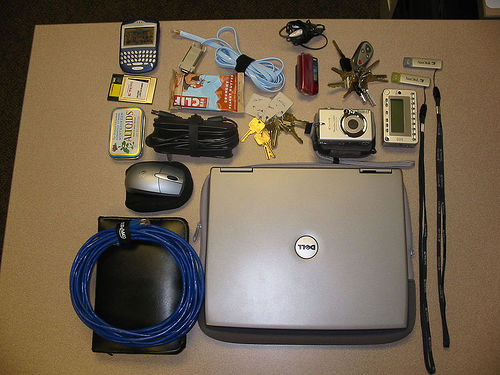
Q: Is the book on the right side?
A: No, the book is on the left of the image.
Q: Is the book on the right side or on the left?
A: The book is on the left of the image.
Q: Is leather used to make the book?
A: Yes, the book is made of leather.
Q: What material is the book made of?
A: The book is made of leather.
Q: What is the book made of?
A: The book is made of leather.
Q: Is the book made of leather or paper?
A: The book is made of leather.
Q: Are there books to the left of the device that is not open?
A: Yes, there is a book to the left of the laptop computer.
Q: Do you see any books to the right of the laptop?
A: No, the book is to the left of the laptop.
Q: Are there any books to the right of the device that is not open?
A: No, the book is to the left of the laptop.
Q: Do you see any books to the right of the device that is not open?
A: No, the book is to the left of the laptop.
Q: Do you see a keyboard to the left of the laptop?
A: No, there is a book to the left of the laptop.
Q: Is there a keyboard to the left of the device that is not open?
A: No, there is a book to the left of the laptop.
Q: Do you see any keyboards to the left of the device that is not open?
A: No, there is a book to the left of the laptop.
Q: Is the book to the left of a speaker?
A: No, the book is to the left of the laptop.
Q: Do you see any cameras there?
A: Yes, there is a camera.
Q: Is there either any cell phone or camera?
A: Yes, there is a camera.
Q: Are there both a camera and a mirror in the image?
A: No, there is a camera but no mirrors.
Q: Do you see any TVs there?
A: No, there are no tvs.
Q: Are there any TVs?
A: No, there are no tvs.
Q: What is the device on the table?
A: The device is a camera.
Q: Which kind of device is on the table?
A: The device is a camera.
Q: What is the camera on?
A: The camera is on the table.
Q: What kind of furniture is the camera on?
A: The camera is on the table.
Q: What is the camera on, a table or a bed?
A: The camera is on a table.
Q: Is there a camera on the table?
A: Yes, there is a camera on the table.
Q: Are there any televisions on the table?
A: No, there is a camera on the table.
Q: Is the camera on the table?
A: Yes, the camera is on the table.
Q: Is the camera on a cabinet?
A: No, the camera is on the table.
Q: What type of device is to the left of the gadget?
A: The device is a camera.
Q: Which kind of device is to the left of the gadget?
A: The device is a camera.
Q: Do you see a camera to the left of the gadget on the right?
A: Yes, there is a camera to the left of the gadget.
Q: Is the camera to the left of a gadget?
A: Yes, the camera is to the left of a gadget.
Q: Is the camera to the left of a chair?
A: No, the camera is to the left of a gadget.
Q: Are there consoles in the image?
A: No, there are no consoles.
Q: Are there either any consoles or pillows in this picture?
A: No, there are no consoles or pillows.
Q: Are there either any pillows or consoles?
A: No, there are no consoles or pillows.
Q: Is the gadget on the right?
A: Yes, the gadget is on the right of the image.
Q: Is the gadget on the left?
A: No, the gadget is on the right of the image.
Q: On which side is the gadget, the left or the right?
A: The gadget is on the right of the image.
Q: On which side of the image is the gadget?
A: The gadget is on the right of the image.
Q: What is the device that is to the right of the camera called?
A: The device is a gadget.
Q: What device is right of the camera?
A: The device is a gadget.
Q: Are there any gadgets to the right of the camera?
A: Yes, there is a gadget to the right of the camera.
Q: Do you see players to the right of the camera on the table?
A: No, there is a gadget to the right of the camera.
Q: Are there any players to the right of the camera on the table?
A: No, there is a gadget to the right of the camera.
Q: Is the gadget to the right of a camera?
A: Yes, the gadget is to the right of a camera.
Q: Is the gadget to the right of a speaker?
A: No, the gadget is to the right of a camera.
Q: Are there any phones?
A: Yes, there is a phone.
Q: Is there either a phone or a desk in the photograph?
A: Yes, there is a phone.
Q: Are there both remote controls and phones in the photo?
A: Yes, there are both a phone and a remote control.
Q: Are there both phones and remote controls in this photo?
A: Yes, there are both a phone and a remote control.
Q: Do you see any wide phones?
A: Yes, there is a wide phone.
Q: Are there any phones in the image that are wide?
A: Yes, there is a phone that is wide.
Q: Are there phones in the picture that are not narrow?
A: Yes, there is a wide phone.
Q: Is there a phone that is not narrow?
A: Yes, there is a wide phone.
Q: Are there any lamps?
A: No, there are no lamps.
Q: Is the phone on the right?
A: No, the phone is on the left of the image.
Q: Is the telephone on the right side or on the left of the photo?
A: The telephone is on the left of the image.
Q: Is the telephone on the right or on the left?
A: The telephone is on the left of the image.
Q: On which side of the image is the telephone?
A: The telephone is on the left of the image.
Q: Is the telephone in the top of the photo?
A: Yes, the telephone is in the top of the image.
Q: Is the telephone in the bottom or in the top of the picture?
A: The telephone is in the top of the image.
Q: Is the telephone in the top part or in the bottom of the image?
A: The telephone is in the top of the image.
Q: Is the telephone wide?
A: Yes, the telephone is wide.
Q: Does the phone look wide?
A: Yes, the phone is wide.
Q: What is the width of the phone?
A: The phone is wide.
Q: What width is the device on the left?
A: The phone is wide.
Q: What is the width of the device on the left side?
A: The phone is wide.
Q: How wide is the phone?
A: The phone is wide.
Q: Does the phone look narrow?
A: No, the phone is wide.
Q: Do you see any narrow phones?
A: No, there is a phone but it is wide.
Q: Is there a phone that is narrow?
A: No, there is a phone but it is wide.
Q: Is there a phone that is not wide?
A: No, there is a phone but it is wide.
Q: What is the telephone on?
A: The telephone is on the table.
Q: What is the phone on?
A: The telephone is on the table.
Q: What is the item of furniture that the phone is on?
A: The piece of furniture is a table.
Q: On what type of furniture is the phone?
A: The phone is on the table.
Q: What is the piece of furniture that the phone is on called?
A: The piece of furniture is a table.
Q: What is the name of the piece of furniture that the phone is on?
A: The piece of furniture is a table.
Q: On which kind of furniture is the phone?
A: The phone is on the table.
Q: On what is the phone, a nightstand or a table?
A: The phone is on a table.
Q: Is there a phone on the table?
A: Yes, there is a phone on the table.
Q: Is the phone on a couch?
A: No, the phone is on the table.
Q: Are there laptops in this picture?
A: Yes, there is a laptop.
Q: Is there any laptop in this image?
A: Yes, there is a laptop.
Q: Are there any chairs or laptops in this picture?
A: Yes, there is a laptop.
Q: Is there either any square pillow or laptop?
A: Yes, there is a square laptop.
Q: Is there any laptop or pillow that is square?
A: Yes, the laptop is square.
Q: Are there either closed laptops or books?
A: Yes, there is a closed laptop.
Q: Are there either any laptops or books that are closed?
A: Yes, the laptop is closed.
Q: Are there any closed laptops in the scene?
A: Yes, there is a closed laptop.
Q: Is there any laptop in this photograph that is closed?
A: Yes, there is a laptop that is closed.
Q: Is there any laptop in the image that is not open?
A: Yes, there is an closed laptop.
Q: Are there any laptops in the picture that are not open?
A: Yes, there is an closed laptop.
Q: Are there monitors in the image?
A: No, there are no monitors.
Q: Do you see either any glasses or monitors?
A: No, there are no monitors or glasses.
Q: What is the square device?
A: The device is a laptop.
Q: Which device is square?
A: The device is a laptop.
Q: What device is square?
A: The device is a laptop.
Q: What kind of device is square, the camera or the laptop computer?
A: The laptop computer is square.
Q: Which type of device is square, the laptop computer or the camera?
A: The laptop computer is square.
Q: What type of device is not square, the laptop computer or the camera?
A: The camera is not square.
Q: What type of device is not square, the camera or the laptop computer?
A: The camera is not square.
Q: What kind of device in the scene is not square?
A: The device is a camera.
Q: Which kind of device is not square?
A: The device is a camera.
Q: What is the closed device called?
A: The device is a laptop.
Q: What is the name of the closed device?
A: The device is a laptop.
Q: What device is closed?
A: The device is a laptop.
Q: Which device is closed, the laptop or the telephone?
A: The laptop is closed.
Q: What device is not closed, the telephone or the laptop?
A: The telephone is not closed.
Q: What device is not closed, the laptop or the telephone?
A: The telephone is not closed.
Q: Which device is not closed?
A: The device is a phone.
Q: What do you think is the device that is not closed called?
A: The device is a phone.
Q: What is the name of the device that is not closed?
A: The device is a phone.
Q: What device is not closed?
A: The device is a phone.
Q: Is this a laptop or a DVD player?
A: This is a laptop.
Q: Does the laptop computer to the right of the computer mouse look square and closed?
A: Yes, the laptop computer is square and closed.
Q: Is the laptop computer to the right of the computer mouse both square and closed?
A: Yes, the laptop computer is square and closed.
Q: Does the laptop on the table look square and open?
A: No, the laptop is square but closed.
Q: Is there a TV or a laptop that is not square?
A: No, there is a laptop but it is square.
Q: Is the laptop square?
A: Yes, the laptop is square.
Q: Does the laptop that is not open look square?
A: Yes, the laptop is square.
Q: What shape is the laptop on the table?
A: The laptop is square.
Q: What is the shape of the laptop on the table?
A: The laptop is square.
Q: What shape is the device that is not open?
A: The laptop is square.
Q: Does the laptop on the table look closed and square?
A: Yes, the laptop is closed and square.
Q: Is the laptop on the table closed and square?
A: Yes, the laptop is closed and square.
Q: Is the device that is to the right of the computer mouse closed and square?
A: Yes, the laptop is closed and square.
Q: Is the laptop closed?
A: Yes, the laptop is closed.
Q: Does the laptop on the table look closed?
A: Yes, the laptop is closed.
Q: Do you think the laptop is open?
A: No, the laptop is closed.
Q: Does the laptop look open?
A: No, the laptop is closed.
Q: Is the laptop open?
A: No, the laptop is closed.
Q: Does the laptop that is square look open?
A: No, the laptop computer is closed.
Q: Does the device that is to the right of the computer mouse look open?
A: No, the laptop computer is closed.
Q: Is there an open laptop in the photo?
A: No, there is a laptop but it is closed.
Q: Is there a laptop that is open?
A: No, there is a laptop but it is closed.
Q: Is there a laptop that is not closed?
A: No, there is a laptop but it is closed.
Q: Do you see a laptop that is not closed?
A: No, there is a laptop but it is closed.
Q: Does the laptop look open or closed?
A: The laptop is closed.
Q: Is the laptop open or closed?
A: The laptop is closed.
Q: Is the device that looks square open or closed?
A: The laptop is closed.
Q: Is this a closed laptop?
A: Yes, this is a closed laptop.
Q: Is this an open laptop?
A: No, this is a closed laptop.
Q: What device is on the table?
A: The device is a laptop.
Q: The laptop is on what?
A: The laptop is on the table.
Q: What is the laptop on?
A: The laptop is on the table.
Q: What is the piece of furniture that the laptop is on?
A: The piece of furniture is a table.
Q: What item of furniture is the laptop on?
A: The laptop is on the table.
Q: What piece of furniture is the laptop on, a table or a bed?
A: The laptop is on a table.